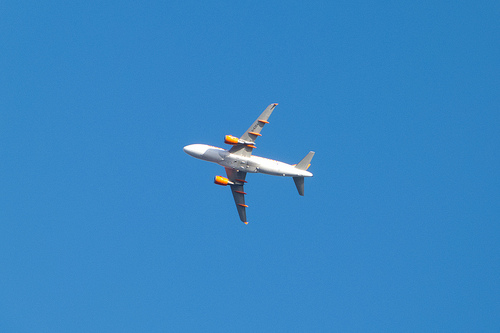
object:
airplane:
[183, 103, 316, 225]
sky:
[1, 0, 500, 332]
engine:
[224, 135, 244, 145]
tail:
[283, 162, 314, 177]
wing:
[228, 103, 279, 159]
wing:
[224, 167, 249, 225]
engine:
[213, 175, 234, 186]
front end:
[183, 143, 209, 159]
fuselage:
[201, 144, 279, 176]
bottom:
[183, 147, 313, 178]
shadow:
[203, 143, 252, 161]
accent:
[274, 103, 278, 105]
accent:
[258, 119, 269, 124]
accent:
[248, 131, 262, 136]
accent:
[246, 144, 256, 149]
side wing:
[295, 151, 316, 171]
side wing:
[292, 176, 304, 196]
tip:
[182, 146, 187, 152]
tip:
[308, 172, 313, 177]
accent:
[236, 178, 248, 184]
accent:
[233, 190, 246, 196]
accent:
[237, 203, 247, 208]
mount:
[240, 138, 255, 145]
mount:
[230, 180, 245, 185]